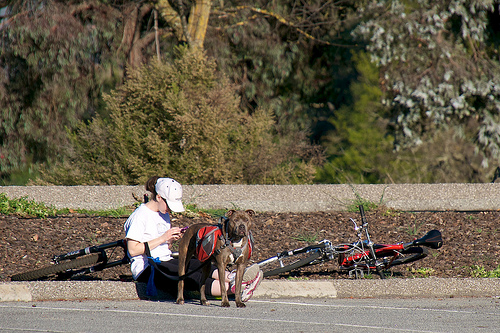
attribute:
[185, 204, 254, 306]
brown dog — standing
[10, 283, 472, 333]
parking lot — grey